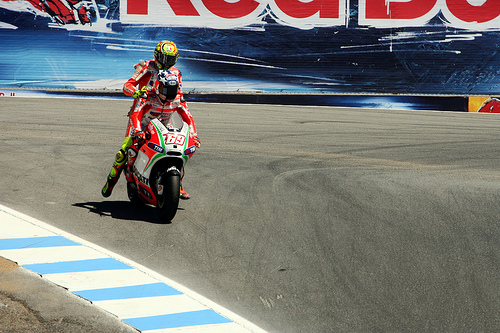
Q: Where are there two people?
A: On a motorcycle.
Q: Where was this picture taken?
A: In a race track.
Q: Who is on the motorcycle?
A: Two riders.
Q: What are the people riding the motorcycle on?
A: Pavement.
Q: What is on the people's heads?
A: Helmets.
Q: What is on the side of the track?
A: Blue and white lines.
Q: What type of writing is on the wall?
A: Red and white block letters.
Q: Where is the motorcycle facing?
A: Forward.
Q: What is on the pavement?
A: Tire tracks.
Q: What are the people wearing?
A: Racing gear.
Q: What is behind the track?
A: A blue wall.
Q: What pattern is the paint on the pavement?
A: Striped.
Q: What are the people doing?
A: Riding Motorcycle.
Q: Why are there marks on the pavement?
A: From Motorcycles.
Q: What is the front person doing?
A: Driving the motorcycle.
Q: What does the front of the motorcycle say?
A: 69.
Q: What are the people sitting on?
A: A motorcycle.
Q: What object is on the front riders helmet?
A: A star.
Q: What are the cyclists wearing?
A: Bodysuits.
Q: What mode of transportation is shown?
A: Motorcycle.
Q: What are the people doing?
A: Riding a motorcycles.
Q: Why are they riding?
A: Performing.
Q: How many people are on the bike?
A: 2.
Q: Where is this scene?
A: Raceway.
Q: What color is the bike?
A: Red, green and white.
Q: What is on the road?
A: Blue and white stripes.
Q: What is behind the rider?
A: Painted sign.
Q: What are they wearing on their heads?
A: Helmets.